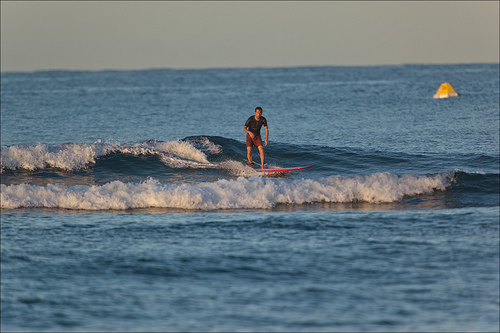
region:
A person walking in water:
[230, 102, 307, 162]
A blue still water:
[329, 234, 463, 305]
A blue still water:
[163, 226, 282, 308]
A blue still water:
[13, 221, 154, 305]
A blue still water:
[405, 111, 497, 150]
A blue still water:
[292, 77, 383, 146]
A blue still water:
[137, 59, 211, 121]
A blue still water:
[99, 102, 184, 137]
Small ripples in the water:
[5, 175, 37, 212]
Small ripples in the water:
[1, 278, 43, 318]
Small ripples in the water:
[51, 280, 113, 323]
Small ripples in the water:
[95, 277, 152, 326]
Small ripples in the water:
[144, 282, 211, 332]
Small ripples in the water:
[188, 284, 260, 318]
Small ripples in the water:
[243, 287, 293, 329]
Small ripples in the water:
[276, 284, 316, 331]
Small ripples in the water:
[307, 283, 379, 322]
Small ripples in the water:
[374, 279, 407, 314]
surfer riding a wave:
[241, 103, 311, 174]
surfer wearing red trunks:
[241, 106, 311, 173]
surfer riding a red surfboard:
[236, 106, 308, 174]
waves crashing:
[4, 135, 491, 214]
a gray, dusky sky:
[7, 7, 492, 70]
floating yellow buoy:
[430, 76, 455, 101]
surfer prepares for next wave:
[235, 105, 310, 175]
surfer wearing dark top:
[236, 105, 309, 175]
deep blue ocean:
[5, 75, 490, 311]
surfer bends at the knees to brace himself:
[235, 103, 310, 173]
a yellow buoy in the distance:
[432, 80, 457, 99]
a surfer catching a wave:
[240, 105, 306, 172]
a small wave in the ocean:
[5, 132, 482, 212]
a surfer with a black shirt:
[222, 106, 316, 177]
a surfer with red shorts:
[230, 107, 310, 177]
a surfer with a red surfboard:
[228, 107, 311, 175]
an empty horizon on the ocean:
[3, 59, 497, 141]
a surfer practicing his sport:
[235, 105, 315, 175]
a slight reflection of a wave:
[1, 187, 454, 218]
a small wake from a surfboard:
[215, 159, 305, 179]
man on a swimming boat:
[239, 103, 316, 170]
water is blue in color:
[348, 242, 447, 298]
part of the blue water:
[334, 264, 407, 311]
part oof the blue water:
[84, 217, 144, 285]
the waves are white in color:
[175, 183, 275, 210]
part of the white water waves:
[351, 180, 410, 207]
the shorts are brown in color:
[247, 130, 271, 147]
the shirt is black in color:
[246, 108, 273, 132]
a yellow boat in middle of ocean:
[437, 65, 462, 102]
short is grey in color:
[251, 136, 273, 146]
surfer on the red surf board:
[243, 103, 273, 173]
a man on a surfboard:
[246, 106, 266, 168]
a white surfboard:
[258, 164, 313, 174]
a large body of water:
[0, 66, 498, 331]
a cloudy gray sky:
[0, 0, 498, 67]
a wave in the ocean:
[0, 137, 498, 202]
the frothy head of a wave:
[0, 172, 445, 209]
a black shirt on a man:
[246, 114, 266, 134]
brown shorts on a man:
[244, 135, 261, 149]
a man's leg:
[256, 137, 266, 170]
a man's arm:
[262, 118, 269, 144]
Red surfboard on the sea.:
[256, 164, 312, 175]